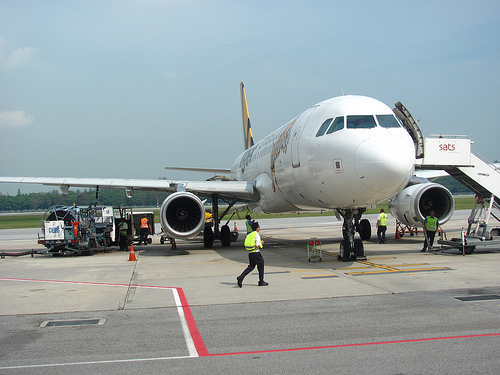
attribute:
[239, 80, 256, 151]
wing — airplane's 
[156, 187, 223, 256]
plane engine — plane 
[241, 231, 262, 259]
vest — yellow 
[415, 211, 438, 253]
employee — uniformed airport 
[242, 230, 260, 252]
vest — green reflective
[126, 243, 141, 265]
cone — orange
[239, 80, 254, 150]
fin — blue , yellow 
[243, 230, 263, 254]
vest — neon green 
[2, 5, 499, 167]
sky — part, blue 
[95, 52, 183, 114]
sky — blue 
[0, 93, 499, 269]
airplane — white 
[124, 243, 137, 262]
cone — white , orange 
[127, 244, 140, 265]
safety cone — orange safety 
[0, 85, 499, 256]
airplane — big white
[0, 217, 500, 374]
runway — airport 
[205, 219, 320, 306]
worker — airport 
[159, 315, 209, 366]
line — long red , white 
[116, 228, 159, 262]
cone — white , orange 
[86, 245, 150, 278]
orange cone — orange 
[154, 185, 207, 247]
engine — airplane's right jet 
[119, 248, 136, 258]
stripe — white